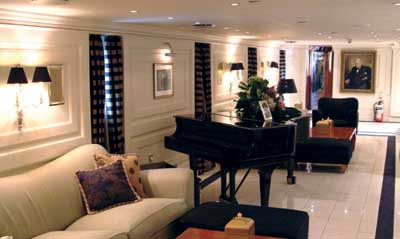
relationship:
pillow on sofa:
[67, 154, 144, 219] [1, 140, 198, 234]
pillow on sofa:
[73, 157, 144, 212] [1, 140, 198, 234]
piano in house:
[197, 58, 391, 210] [0, 0, 399, 238]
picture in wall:
[151, 61, 175, 97] [1, 23, 302, 176]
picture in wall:
[148, 58, 177, 102] [1, 23, 302, 176]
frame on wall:
[152, 62, 176, 99] [0, 22, 293, 164]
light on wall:
[5, 61, 31, 136] [1, 9, 307, 174]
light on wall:
[23, 60, 53, 114] [1, 9, 307, 174]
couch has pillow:
[1, 148, 189, 237] [77, 162, 135, 207]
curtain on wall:
[87, 33, 129, 146] [87, 71, 126, 122]